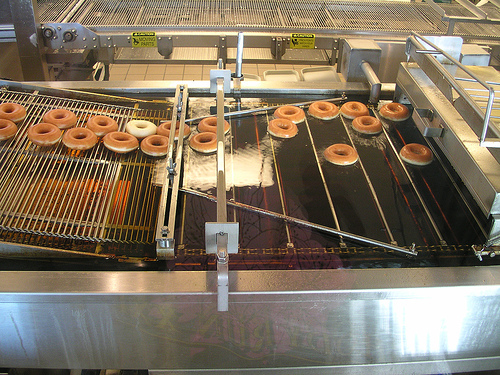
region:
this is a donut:
[307, 133, 365, 165]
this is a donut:
[399, 126, 432, 173]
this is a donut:
[262, 115, 302, 156]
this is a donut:
[142, 133, 188, 168]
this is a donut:
[58, 118, 95, 163]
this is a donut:
[25, 111, 72, 150]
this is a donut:
[74, 102, 119, 145]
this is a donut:
[182, 125, 230, 165]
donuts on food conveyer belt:
[2, 84, 432, 201]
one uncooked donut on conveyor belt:
[122, 115, 154, 135]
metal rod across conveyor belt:
[201, 58, 250, 308]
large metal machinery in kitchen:
[0, 61, 498, 373]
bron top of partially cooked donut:
[306, 99, 338, 117]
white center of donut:
[104, 138, 138, 154]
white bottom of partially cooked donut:
[326, 155, 358, 166]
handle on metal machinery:
[405, 98, 447, 143]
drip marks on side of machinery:
[5, 306, 120, 373]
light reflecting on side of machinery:
[372, 289, 471, 368]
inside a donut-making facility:
[15, 6, 472, 301]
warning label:
[125, 25, 155, 50]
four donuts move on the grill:
[30, 100, 100, 155]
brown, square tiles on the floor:
[115, 55, 200, 75]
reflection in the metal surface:
[90, 295, 435, 365]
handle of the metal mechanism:
[406, 95, 442, 135]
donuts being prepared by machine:
[0, 85, 430, 185]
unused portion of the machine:
[10, 0, 415, 65]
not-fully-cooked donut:
[125, 115, 155, 135]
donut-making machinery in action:
[2, 5, 494, 340]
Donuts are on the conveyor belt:
[15, 97, 463, 179]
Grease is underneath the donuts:
[70, 133, 427, 204]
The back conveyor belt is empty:
[100, 10, 367, 55]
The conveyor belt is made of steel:
[27, 154, 497, 334]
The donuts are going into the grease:
[33, 97, 420, 202]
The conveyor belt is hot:
[33, 100, 149, 225]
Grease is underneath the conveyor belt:
[238, 147, 428, 236]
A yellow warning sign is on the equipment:
[120, 25, 190, 55]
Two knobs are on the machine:
[39, 24, 117, 63]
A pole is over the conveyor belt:
[210, 60, 259, 302]